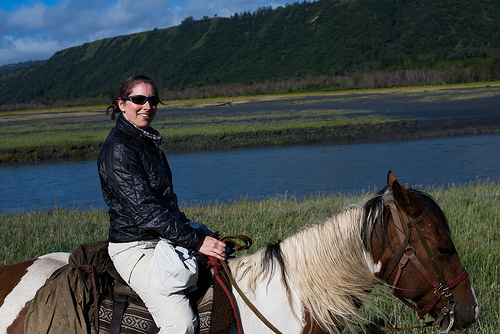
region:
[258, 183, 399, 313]
horse's mane is white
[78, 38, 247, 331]
woman sitting on a horse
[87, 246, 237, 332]
blanket under the saddle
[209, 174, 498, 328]
horse is brown and white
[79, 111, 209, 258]
jacket is black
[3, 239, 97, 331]
bag on the back of the saddle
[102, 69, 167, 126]
woman's hair is up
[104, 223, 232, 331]
woman's pants are off white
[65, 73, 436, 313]
a woman sitting on a horse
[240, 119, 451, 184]
a body of water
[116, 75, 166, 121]
a woman wearing sunglasses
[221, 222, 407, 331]
a brown and white horse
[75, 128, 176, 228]
a woman wearing a black jacket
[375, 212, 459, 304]
a horse wearing a bridle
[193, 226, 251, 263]
a woman holding horse harness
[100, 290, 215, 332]
a blanket on a horse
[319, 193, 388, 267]
white and black horse's maine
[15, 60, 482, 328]
a woman rides a horse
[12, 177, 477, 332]
the horse is brown and white in color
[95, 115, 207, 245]
the woman wears a black jacket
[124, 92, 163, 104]
the woman wears sunglasses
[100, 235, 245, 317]
the woman sits in a saddle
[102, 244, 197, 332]
the woman is wearing pants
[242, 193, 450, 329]
the horse has a white and black mane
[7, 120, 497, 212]
water is behind the woman and horse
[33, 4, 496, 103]
the hillside is green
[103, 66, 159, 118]
the woman's hair is pulled back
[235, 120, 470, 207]
a body of water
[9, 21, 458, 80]
a mountain covered with trees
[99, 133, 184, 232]
a woman wearing a black jacket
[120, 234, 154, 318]
a woman wearing tan pants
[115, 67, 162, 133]
a woman with brown hair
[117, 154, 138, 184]
the coat is black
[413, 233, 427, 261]
the horse is brown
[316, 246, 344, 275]
the hair is white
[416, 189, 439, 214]
the hair is black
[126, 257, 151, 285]
the pants are white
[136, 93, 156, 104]
she is wearing sunglasses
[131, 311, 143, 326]
the blanket is brown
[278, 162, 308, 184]
the water is blue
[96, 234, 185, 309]
she is riding the horse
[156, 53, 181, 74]
the hill has trees on it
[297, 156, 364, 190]
the water is blue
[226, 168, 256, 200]
the blue water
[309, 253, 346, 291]
the horses hair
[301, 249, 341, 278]
hair on the horse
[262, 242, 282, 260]
the horses hair is black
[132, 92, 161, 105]
the women is wearing glasses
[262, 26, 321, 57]
grass on the mountain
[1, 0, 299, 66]
Blue sky with grey clouds.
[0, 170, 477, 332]
Brown and white horse.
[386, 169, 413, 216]
Horses brown ears.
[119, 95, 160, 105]
Black sunglasses on a face.